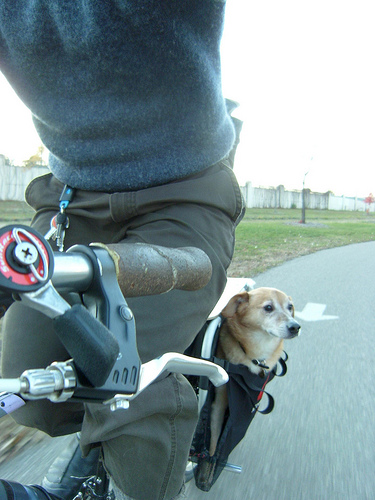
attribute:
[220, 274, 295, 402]
dog — looking, enjoying, brown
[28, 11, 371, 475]
photo — day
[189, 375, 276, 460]
bag — black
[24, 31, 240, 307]
person — riding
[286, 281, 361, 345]
arrow — white, pointing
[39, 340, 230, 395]
brake — silver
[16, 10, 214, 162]
sweater — blue, grey, gray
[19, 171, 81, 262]
keys — set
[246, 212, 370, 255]
grass — green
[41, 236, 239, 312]
handle — brake, grey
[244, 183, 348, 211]
fence — long, wooden, white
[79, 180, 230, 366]
pants — colored, dark, black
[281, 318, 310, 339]
nose — black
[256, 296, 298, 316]
eyes — dark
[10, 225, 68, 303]
background — red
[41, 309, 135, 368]
changer — black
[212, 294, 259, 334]
ears — floppy